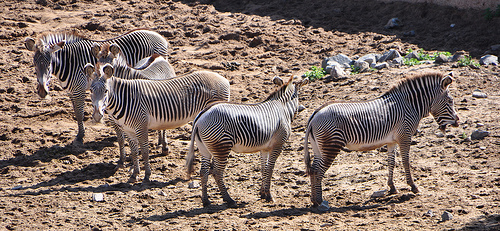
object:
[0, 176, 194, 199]
shadow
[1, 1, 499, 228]
ground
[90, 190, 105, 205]
paper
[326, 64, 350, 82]
rock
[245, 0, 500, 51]
mound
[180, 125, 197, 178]
tail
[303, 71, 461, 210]
zebra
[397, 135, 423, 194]
leg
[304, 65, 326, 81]
plant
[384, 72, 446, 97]
mane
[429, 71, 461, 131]
head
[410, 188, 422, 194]
hoof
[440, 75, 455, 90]
ear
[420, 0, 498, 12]
wall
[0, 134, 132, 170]
shadow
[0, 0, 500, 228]
sand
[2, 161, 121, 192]
shadow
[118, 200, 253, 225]
shadow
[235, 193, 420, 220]
shadow